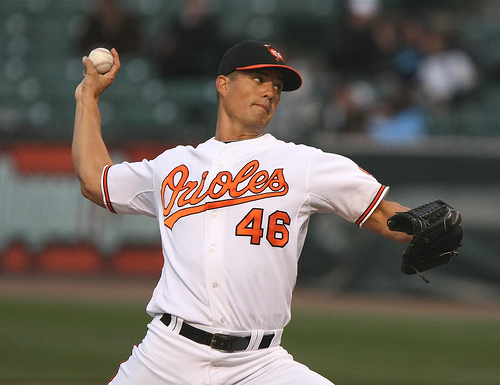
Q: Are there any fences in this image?
A: No, there are no fences.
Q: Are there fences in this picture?
A: No, there are no fences.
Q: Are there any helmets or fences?
A: No, there are no fences or helmets.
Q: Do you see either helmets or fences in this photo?
A: No, there are no fences or helmets.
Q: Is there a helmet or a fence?
A: No, there are no fences or helmets.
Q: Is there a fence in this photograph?
A: No, there are no fences.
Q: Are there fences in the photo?
A: No, there are no fences.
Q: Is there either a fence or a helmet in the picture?
A: No, there are no fences or helmets.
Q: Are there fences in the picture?
A: No, there are no fences.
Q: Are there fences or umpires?
A: No, there are no fences or umpires.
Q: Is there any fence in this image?
A: No, there are no fences.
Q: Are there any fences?
A: No, there are no fences.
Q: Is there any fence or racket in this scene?
A: No, there are no fences or rackets.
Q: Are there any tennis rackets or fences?
A: No, there are no fences or tennis rackets.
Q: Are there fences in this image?
A: No, there are no fences.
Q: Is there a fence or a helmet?
A: No, there are no fences or helmets.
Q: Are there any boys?
A: No, there are no boys.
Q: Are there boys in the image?
A: No, there are no boys.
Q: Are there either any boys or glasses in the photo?
A: No, there are no boys or glasses.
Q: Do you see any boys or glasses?
A: No, there are no boys or glasses.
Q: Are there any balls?
A: Yes, there is a ball.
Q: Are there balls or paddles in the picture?
A: Yes, there is a ball.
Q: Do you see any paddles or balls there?
A: Yes, there is a ball.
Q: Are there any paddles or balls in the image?
A: Yes, there is a ball.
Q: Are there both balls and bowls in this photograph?
A: No, there is a ball but no bowls.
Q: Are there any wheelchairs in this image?
A: No, there are no wheelchairs.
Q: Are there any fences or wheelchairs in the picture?
A: No, there are no wheelchairs or fences.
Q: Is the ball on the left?
A: Yes, the ball is on the left of the image.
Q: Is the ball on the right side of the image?
A: No, the ball is on the left of the image.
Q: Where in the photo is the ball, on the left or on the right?
A: The ball is on the left of the image.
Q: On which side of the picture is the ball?
A: The ball is on the left of the image.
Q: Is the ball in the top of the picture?
A: Yes, the ball is in the top of the image.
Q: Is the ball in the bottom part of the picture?
A: No, the ball is in the top of the image.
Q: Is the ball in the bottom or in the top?
A: The ball is in the top of the image.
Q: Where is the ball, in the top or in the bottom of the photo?
A: The ball is in the top of the image.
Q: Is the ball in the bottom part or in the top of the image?
A: The ball is in the top of the image.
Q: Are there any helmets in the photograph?
A: No, there are no helmets.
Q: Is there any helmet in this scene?
A: No, there are no helmets.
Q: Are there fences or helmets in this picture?
A: No, there are no helmets or fences.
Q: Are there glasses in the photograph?
A: No, there are no glasses.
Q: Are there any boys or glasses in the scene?
A: No, there are no glasses or boys.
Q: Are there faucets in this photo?
A: No, there are no faucets.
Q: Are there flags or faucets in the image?
A: No, there are no faucets or flags.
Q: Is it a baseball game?
A: Yes, that is a baseball game.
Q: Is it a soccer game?
A: No, that is a baseball game.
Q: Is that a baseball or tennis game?
A: That is a baseball game.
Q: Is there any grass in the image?
A: Yes, there is grass.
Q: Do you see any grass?
A: Yes, there is grass.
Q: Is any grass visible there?
A: Yes, there is grass.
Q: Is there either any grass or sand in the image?
A: Yes, there is grass.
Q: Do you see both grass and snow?
A: No, there is grass but no snow.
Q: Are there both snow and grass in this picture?
A: No, there is grass but no snow.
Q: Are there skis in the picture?
A: No, there are no skis.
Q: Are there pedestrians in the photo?
A: No, there are no pedestrians.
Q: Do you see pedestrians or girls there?
A: No, there are no pedestrians or girls.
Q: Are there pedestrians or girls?
A: No, there are no pedestrians or girls.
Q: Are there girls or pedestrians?
A: No, there are no pedestrians or girls.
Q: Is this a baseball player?
A: Yes, this is a baseball player.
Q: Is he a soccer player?
A: No, this is a baseball player.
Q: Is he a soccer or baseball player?
A: This is a baseball player.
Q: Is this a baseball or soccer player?
A: This is a baseball player.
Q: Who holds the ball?
A: The player holds the ball.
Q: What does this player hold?
A: The player holds the ball.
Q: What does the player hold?
A: The player holds the ball.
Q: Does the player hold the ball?
A: Yes, the player holds the ball.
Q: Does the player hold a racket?
A: No, the player holds the ball.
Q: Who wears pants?
A: The player wears pants.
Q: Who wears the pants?
A: The player wears pants.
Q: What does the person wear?
A: The player wears trousers.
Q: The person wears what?
A: The player wears trousers.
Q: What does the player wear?
A: The player wears trousers.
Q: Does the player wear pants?
A: Yes, the player wears pants.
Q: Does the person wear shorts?
A: No, the player wears pants.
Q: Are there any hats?
A: Yes, there is a hat.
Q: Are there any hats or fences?
A: Yes, there is a hat.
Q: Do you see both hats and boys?
A: No, there is a hat but no boys.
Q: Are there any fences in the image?
A: No, there are no fences.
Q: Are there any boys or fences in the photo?
A: No, there are no fences or boys.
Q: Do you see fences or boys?
A: No, there are no fences or boys.